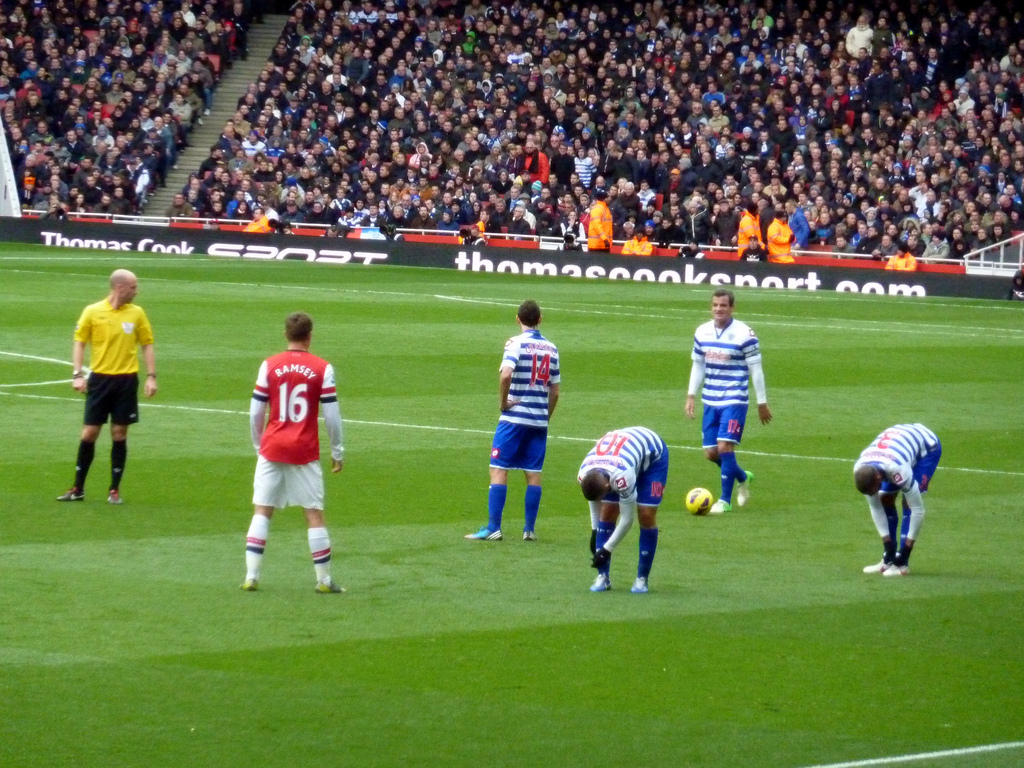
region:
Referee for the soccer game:
[66, 267, 159, 524]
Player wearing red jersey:
[249, 316, 348, 602]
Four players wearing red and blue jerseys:
[473, 290, 941, 584]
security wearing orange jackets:
[243, 192, 810, 266]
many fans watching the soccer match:
[2, 0, 1017, 273]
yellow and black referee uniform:
[74, 297, 157, 421]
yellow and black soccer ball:
[689, 489, 712, 512]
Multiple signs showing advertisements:
[5, 221, 1021, 295]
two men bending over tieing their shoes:
[581, 425, 943, 591]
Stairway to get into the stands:
[132, 6, 301, 215]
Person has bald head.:
[94, 260, 151, 292]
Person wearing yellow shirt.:
[63, 296, 169, 360]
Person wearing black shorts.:
[75, 366, 165, 420]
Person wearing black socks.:
[69, 433, 139, 490]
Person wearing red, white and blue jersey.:
[227, 356, 387, 464]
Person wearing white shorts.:
[245, 439, 345, 498]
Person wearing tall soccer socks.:
[227, 514, 379, 579]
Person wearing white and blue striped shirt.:
[496, 325, 574, 430]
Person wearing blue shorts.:
[467, 418, 569, 475]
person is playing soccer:
[250, 318, 349, 597]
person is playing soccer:
[466, 300, 561, 538]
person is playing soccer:
[576, 422, 668, 588]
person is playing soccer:
[857, 417, 941, 577]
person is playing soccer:
[64, 264, 159, 505]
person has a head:
[288, 312, 317, 348]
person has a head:
[518, 297, 539, 329]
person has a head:
[586, 471, 609, 500]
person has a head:
[712, 293, 733, 325]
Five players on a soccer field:
[201, 217, 985, 688]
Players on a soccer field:
[225, 281, 685, 611]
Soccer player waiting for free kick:
[421, 270, 580, 568]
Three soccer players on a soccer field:
[430, 240, 797, 659]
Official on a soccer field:
[29, 231, 192, 570]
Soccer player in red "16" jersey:
[206, 269, 375, 674]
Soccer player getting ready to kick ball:
[658, 263, 792, 546]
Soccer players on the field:
[53, 272, 946, 589]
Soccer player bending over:
[571, 422, 669, 600]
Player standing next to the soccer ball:
[680, 282, 775, 523]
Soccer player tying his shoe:
[850, 416, 946, 578]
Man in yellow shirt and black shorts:
[57, 263, 162, 508]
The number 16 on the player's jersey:
[277, 377, 312, 432]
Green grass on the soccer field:
[2, 251, 1015, 761]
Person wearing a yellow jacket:
[581, 184, 619, 252]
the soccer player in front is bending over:
[580, 423, 669, 598]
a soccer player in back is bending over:
[852, 415, 942, 572]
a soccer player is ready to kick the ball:
[684, 290, 776, 513]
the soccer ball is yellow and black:
[684, 485, 711, 518]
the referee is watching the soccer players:
[62, 270, 161, 499]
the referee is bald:
[64, 270, 159, 506]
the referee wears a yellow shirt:
[70, 303, 153, 376]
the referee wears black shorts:
[81, 374, 143, 426]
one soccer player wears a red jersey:
[236, 317, 345, 596]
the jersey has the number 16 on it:
[235, 352, 344, 463]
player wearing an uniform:
[456, 290, 576, 553]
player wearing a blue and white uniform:
[675, 276, 782, 525]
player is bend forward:
[565, 407, 683, 605]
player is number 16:
[220, 311, 362, 613]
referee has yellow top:
[50, 253, 170, 514]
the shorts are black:
[74, 370, 150, 434]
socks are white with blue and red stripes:
[236, 504, 345, 583]